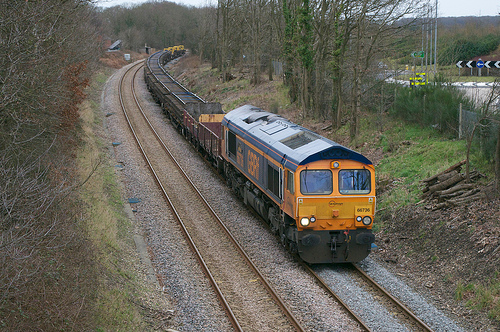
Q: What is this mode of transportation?
A: A train.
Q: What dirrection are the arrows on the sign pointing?
A: To the left.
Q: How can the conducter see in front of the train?
A: By the windows in the front of the train.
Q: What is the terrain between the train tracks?
A: Leveled gravel.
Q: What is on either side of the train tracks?
A: Trees and grass.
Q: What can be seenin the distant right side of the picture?
A: A road.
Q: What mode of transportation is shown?
A: Train.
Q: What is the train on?
A: Tracks.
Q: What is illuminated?
A: Headlights.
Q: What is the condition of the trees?
A: Bare.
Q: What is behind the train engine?
A: Train cars.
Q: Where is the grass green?
A: On the right side of the train.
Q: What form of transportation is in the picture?
A: Train.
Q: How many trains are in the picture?
A: One.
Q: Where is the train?
A: On the tracks.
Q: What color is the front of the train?
A: Yellow.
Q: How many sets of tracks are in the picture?
A: Two.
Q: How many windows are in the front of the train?
A: Two.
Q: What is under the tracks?
A: Gravel.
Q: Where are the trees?
A: Beside the tracks.